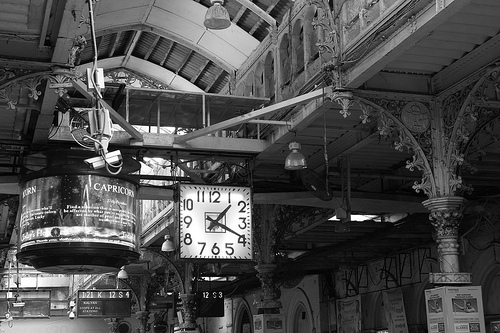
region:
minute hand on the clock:
[220, 214, 248, 242]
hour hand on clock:
[212, 205, 236, 223]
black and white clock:
[166, 164, 301, 283]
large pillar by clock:
[423, 212, 497, 317]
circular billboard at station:
[19, 169, 172, 276]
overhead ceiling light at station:
[282, 146, 317, 175]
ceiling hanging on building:
[118, 45, 261, 102]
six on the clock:
[207, 232, 229, 254]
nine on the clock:
[183, 210, 198, 227]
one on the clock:
[221, 187, 236, 207]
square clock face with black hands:
[174, 175, 253, 260]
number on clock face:
[211, 241, 220, 256]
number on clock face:
[226, 241, 238, 255]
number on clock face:
[198, 240, 205, 254]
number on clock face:
[208, 190, 218, 206]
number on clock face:
[226, 190, 234, 205]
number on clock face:
[192, 188, 204, 203]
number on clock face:
[179, 213, 193, 228]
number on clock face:
[233, 215, 252, 232]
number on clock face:
[238, 199, 249, 213]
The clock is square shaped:
[174, 176, 260, 268]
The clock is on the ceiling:
[162, 175, 267, 271]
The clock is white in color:
[161, 170, 266, 275]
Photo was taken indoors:
[10, 5, 480, 330]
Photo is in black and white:
[10, 86, 495, 317]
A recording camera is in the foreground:
[70, 70, 126, 185]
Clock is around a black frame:
[165, 175, 265, 265]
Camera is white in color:
[65, 131, 140, 186]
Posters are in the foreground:
[420, 283, 481, 329]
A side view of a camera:
[69, 138, 139, 188]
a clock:
[161, 196, 293, 331]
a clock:
[98, 147, 228, 322]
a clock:
[99, 128, 238, 298]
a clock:
[160, 97, 300, 319]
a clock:
[103, 36, 331, 309]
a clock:
[140, 127, 234, 331]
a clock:
[115, 96, 250, 301]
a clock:
[110, 115, 246, 285]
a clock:
[100, 135, 226, 285]